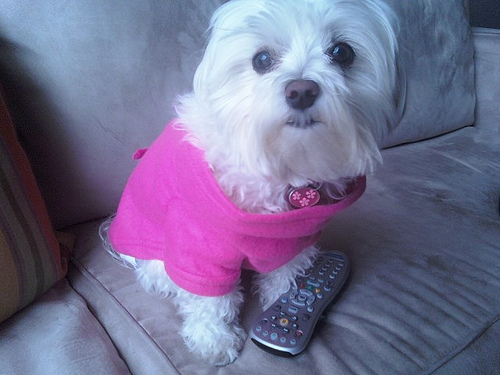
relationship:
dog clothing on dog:
[87, 122, 372, 309] [110, 9, 406, 362]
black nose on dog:
[284, 80, 322, 109] [185, 2, 404, 293]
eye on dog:
[330, 42, 355, 67] [110, 9, 406, 362]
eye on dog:
[252, 49, 272, 71] [110, 9, 406, 362]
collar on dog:
[289, 185, 321, 212] [110, 9, 406, 362]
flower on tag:
[289, 189, 300, 201] [287, 180, 324, 215]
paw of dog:
[173, 300, 242, 367] [110, 9, 406, 362]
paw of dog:
[259, 250, 317, 307] [110, 9, 406, 362]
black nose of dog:
[284, 80, 322, 109] [110, 9, 406, 362]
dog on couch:
[110, 9, 406, 362] [1, 0, 498, 367]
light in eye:
[258, 47, 274, 71] [250, 47, 277, 77]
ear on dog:
[195, 38, 238, 104] [179, 1, 406, 210]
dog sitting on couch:
[110, 9, 406, 362] [1, 0, 498, 367]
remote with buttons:
[241, 220, 369, 372] [276, 290, 303, 345]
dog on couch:
[127, 9, 405, 324] [336, 15, 498, 360]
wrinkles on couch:
[315, 253, 488, 373] [1, 0, 498, 367]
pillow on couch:
[2, 96, 69, 328] [1, 0, 498, 367]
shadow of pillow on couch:
[19, 81, 90, 272] [1, 0, 498, 367]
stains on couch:
[432, 182, 494, 239] [1, 0, 498, 367]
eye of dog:
[327, 41, 355, 67] [110, 9, 406, 362]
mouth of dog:
[286, 111, 323, 133] [110, 9, 406, 362]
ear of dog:
[397, 60, 403, 74] [110, 9, 406, 362]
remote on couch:
[241, 220, 369, 372] [1, 0, 498, 367]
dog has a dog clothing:
[110, 9, 406, 362] [87, 122, 372, 309]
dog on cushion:
[110, 9, 406, 362] [4, 72, 77, 337]